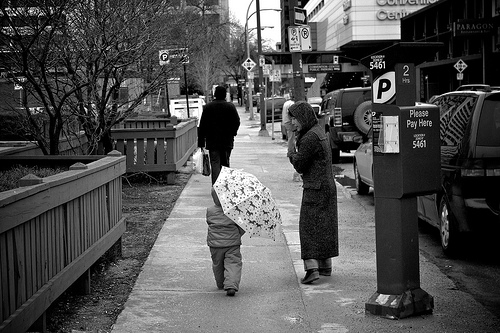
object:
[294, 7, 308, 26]
street sign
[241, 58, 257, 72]
sign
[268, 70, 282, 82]
sign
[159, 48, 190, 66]
sign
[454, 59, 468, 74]
sign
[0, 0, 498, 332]
picture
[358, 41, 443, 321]
meter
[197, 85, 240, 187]
man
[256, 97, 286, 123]
vehicles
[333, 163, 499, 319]
road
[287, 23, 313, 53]
sign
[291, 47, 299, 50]
arrow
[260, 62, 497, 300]
street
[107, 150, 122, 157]
post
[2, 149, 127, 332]
fence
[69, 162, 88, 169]
post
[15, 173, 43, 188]
post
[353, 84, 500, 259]
cars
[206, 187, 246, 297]
child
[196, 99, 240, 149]
clothing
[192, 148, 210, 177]
bag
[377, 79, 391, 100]
letter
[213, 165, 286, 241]
umbrella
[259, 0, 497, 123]
buildings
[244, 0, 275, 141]
curved pole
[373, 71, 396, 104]
sign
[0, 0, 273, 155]
trees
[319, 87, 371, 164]
vehicle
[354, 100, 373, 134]
tire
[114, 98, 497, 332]
sidewalk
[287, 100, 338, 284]
woman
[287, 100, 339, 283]
mother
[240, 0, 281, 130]
light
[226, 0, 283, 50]
white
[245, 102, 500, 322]
street